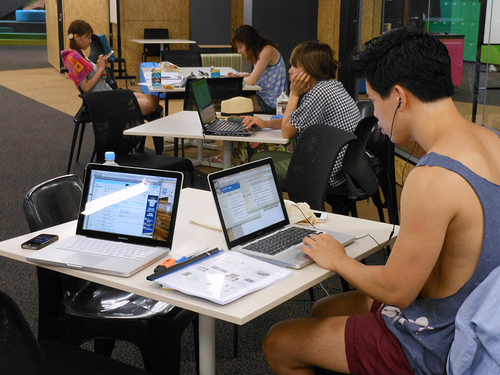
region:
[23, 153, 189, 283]
A laptop on the table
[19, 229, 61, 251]
A cellphone on the table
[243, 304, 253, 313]
Part of the white table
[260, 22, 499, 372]
A person sitting on the chair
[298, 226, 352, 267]
The left hand of the person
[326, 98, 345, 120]
Part of the black and white shirt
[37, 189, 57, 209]
Part of the chair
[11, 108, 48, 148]
Part of the carpet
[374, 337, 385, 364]
Part of the red shorts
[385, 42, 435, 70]
Part of the black hair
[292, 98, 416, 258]
the earphones in the man's ear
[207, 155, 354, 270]
the opened laptop in front of the man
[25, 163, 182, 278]
the opened laptop on the table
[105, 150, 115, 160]
the cap on the plastic bottle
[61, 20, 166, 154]
the woman sitting down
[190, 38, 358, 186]
the woman looking at the laptop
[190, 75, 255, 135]
the laptop in front of the woman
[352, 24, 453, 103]
the dark short hair on the man's head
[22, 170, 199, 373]
the empty chair across the man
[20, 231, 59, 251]
the phone on the table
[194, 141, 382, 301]
the laptop is open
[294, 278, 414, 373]
the young man is wearing shorts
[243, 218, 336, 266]
the keys are black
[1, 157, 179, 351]
the chairs are black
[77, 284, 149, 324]
the light is reflected in the chair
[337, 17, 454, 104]
the young man`s hair is black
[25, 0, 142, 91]
the girl is looking at her phone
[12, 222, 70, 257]
a phone is on the table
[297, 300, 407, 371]
the shorts are burgundy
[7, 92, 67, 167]
the floor is carpeted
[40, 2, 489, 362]
group of people sitting at tables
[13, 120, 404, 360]
table top is white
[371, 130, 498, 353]
man wearing blue shirt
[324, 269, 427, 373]
man wearing maroon shorts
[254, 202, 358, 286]
man with hand on computer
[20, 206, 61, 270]
cell phone on table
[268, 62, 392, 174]
woman wearing plaid shirt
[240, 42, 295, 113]
woman wearing blue shirt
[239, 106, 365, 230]
black chair next to tables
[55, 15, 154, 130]
woman holding an object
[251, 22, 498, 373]
A person in the foreground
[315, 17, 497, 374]
Man is wearing a tank top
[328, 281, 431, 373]
Man is wearing shorts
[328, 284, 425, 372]
The shorts are dark red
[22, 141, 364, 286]
Two laptops in the foreground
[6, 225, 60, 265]
A cell phone on the table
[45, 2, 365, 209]
Three people in the background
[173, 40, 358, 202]
Person is on a laptop in the background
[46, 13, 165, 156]
Young woman is on a electronic device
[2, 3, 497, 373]
Photo was taken indoors